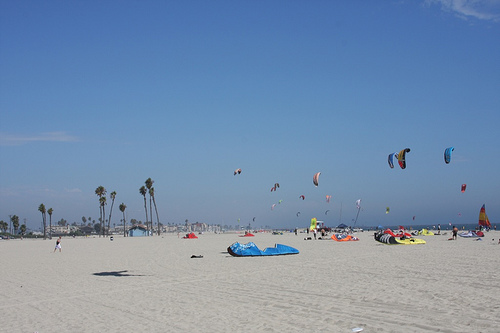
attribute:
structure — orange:
[330, 232, 356, 243]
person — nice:
[52, 235, 63, 254]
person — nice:
[312, 229, 317, 239]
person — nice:
[452, 223, 459, 237]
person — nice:
[436, 223, 441, 233]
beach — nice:
[0, 232, 499, 332]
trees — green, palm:
[86, 174, 145, 211]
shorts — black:
[451, 231, 458, 239]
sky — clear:
[0, 1, 498, 231]